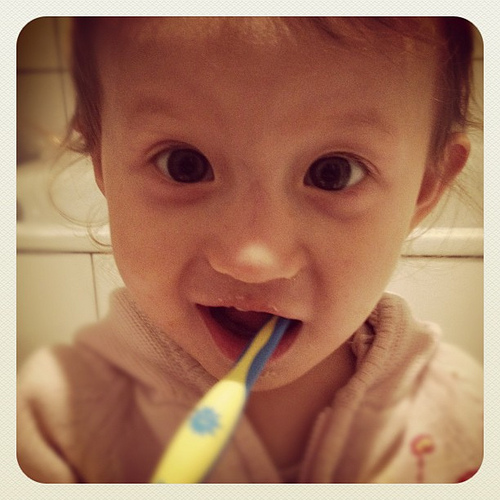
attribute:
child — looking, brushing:
[55, 72, 443, 397]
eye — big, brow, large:
[143, 141, 248, 206]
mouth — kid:
[164, 272, 350, 382]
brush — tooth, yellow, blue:
[106, 305, 299, 457]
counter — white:
[22, 196, 123, 297]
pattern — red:
[5, 205, 93, 281]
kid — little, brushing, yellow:
[117, 48, 443, 388]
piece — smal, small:
[311, 338, 425, 425]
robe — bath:
[337, 320, 454, 456]